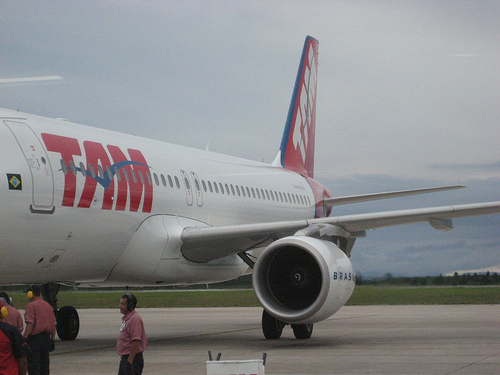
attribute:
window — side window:
[47, 145, 80, 177]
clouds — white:
[8, 13, 498, 183]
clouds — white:
[147, 27, 242, 78]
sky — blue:
[1, 2, 499, 113]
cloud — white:
[418, 76, 458, 120]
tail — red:
[293, 26, 328, 170]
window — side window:
[95, 162, 108, 181]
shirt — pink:
[110, 312, 140, 351]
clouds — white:
[448, 45, 488, 67]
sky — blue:
[11, 7, 493, 122]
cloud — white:
[435, 161, 498, 178]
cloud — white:
[336, 173, 494, 275]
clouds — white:
[106, 52, 206, 110]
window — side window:
[292, 192, 303, 206]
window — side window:
[57, 159, 72, 177]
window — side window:
[104, 158, 114, 188]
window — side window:
[251, 185, 260, 202]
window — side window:
[165, 170, 174, 190]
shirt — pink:
[18, 295, 59, 341]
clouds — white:
[116, 36, 275, 142]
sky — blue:
[33, 9, 470, 238]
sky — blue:
[383, 46, 439, 86]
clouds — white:
[340, 28, 497, 156]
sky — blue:
[3, 3, 498, 155]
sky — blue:
[347, 19, 458, 166]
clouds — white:
[140, 36, 325, 128]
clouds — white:
[333, 149, 475, 329]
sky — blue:
[399, 35, 440, 80]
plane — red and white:
[7, 37, 497, 349]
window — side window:
[170, 172, 182, 190]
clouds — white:
[324, 169, 499, 279]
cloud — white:
[328, 162, 498, 280]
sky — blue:
[1, 0, 498, 271]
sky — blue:
[387, 65, 494, 132]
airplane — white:
[9, 10, 498, 368]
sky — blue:
[28, 13, 336, 88]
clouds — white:
[336, 39, 484, 176]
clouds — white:
[374, 33, 465, 123]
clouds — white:
[321, 35, 488, 165]